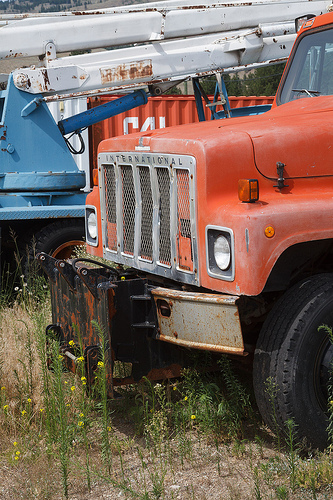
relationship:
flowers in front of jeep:
[96, 360, 104, 369] [45, 13, 333, 454]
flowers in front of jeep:
[24, 396, 33, 402] [45, 13, 333, 454]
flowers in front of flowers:
[120, 275, 125, 280] [96, 360, 104, 369]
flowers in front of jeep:
[70, 384, 76, 391] [45, 13, 333, 454]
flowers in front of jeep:
[66, 338, 75, 345] [45, 13, 333, 454]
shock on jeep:
[59, 87, 147, 139] [45, 13, 333, 454]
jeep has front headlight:
[45, 13, 333, 454] [205, 224, 234, 276]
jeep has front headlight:
[45, 13, 333, 454] [85, 205, 99, 247]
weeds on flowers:
[32, 344, 202, 484] [30, 324, 152, 449]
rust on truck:
[97, 57, 156, 88] [68, 10, 329, 275]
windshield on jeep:
[276, 26, 332, 104] [45, 13, 333, 454]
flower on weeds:
[96, 359, 107, 370] [0, 279, 327, 497]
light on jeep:
[261, 226, 274, 240] [45, 13, 333, 454]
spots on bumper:
[192, 295, 198, 300] [34, 251, 249, 400]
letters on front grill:
[107, 156, 190, 167] [97, 148, 198, 286]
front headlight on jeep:
[82, 205, 100, 247] [45, 13, 333, 454]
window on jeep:
[95, 148, 217, 292] [68, 10, 331, 302]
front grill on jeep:
[97, 148, 198, 286] [45, 13, 333, 454]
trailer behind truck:
[84, 92, 277, 189] [25, 31, 332, 344]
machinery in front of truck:
[23, 241, 154, 417] [66, 36, 331, 324]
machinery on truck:
[11, 4, 261, 83] [28, 61, 331, 387]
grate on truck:
[91, 150, 211, 268] [113, 73, 315, 268]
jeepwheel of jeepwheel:
[257, 273, 331, 459] [251, 266, 331, 445]